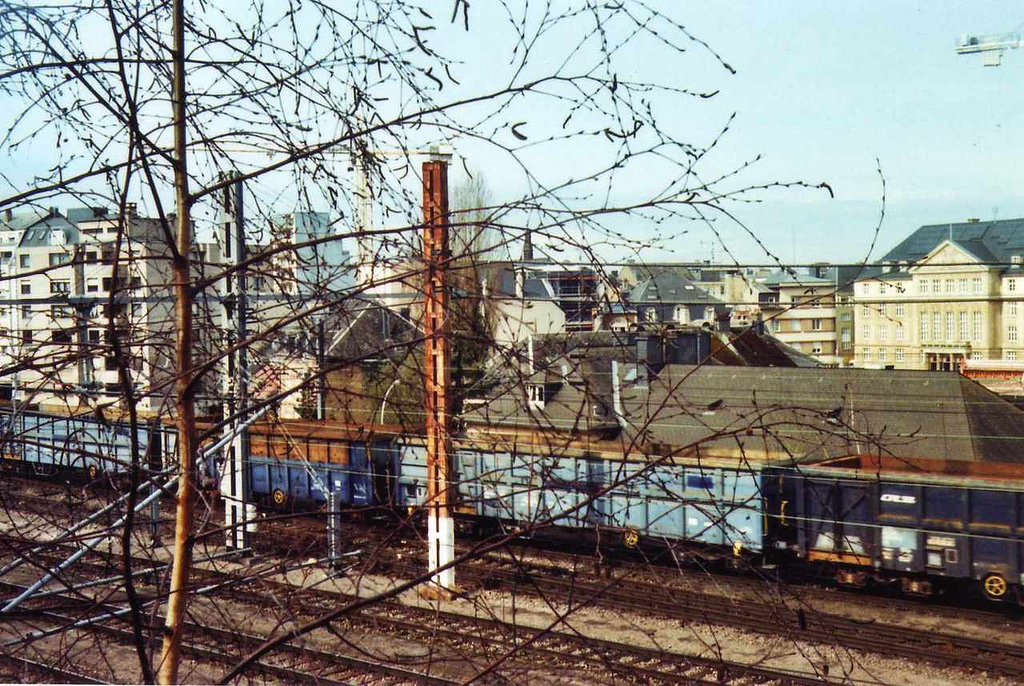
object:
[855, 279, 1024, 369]
wall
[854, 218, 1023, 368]
building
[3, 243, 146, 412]
wall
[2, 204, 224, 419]
building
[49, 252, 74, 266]
window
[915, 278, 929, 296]
window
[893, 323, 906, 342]
window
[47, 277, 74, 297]
window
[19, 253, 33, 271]
window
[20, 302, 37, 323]
window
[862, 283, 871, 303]
window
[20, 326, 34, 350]
window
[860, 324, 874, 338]
window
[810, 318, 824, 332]
window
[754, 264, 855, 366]
building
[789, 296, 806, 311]
window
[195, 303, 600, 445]
branch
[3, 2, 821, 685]
tree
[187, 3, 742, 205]
branch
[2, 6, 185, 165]
branch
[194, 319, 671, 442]
branch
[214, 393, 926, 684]
branch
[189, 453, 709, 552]
branch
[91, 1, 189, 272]
branch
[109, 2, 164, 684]
branch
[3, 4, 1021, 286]
sky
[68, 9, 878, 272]
cloud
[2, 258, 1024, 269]
power line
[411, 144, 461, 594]
tower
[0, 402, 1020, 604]
train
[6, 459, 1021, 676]
track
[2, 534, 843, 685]
track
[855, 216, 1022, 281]
roof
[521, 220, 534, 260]
spire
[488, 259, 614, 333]
building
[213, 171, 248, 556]
pole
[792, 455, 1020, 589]
car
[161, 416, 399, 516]
train car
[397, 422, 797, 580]
train car